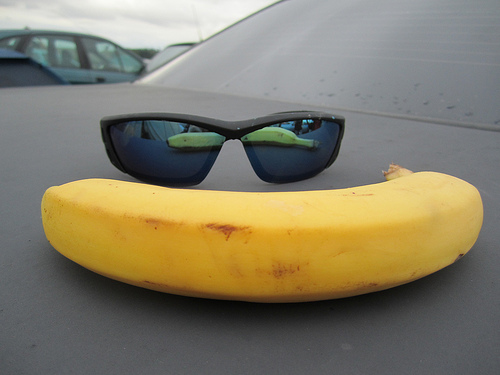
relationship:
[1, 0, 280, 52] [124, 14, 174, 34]
clouds in sky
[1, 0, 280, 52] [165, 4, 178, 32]
clouds in sky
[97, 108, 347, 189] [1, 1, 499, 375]
sunglasses sit on top of car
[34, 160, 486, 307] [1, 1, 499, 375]
banana sits on top of car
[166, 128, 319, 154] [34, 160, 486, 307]
reflection of a banana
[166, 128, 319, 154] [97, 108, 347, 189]
reflection appears in sunglasses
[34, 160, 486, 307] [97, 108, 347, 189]
banana sits in front of sunglasses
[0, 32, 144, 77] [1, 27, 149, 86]
windows of car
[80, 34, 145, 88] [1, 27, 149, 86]
door of car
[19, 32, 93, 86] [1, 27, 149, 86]
door of car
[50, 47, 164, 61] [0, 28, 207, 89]
trees behind cars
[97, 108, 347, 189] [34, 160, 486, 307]
sunglasses are behind banana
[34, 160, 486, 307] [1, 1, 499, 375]
banana atop car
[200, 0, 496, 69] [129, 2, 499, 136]
lines are on window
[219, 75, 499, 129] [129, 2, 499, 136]
dots at bottom of window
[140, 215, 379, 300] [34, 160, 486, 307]
spots on banana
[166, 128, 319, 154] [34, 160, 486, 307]
reflection of banana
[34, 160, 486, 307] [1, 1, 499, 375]
banana sits atop car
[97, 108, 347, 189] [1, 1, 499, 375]
sunglasses sit atop car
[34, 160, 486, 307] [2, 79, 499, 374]
banana sits atop car hood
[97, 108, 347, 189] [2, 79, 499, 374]
sunglasses sit atop car hood